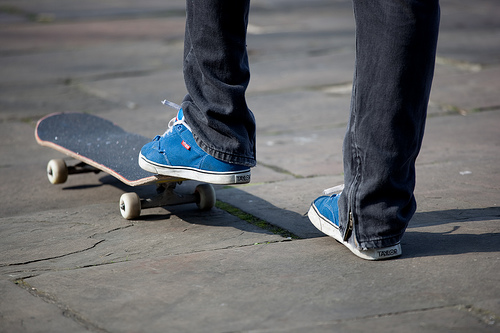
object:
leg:
[173, 0, 251, 114]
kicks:
[137, 120, 250, 185]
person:
[138, 0, 434, 260]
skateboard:
[34, 111, 216, 218]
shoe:
[137, 109, 250, 184]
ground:
[1, 1, 499, 331]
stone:
[6, 218, 496, 332]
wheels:
[118, 194, 141, 219]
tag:
[181, 140, 190, 150]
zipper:
[348, 212, 353, 230]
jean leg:
[342, 0, 438, 209]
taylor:
[376, 249, 397, 257]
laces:
[160, 98, 192, 138]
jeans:
[182, 0, 437, 250]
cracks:
[19, 237, 294, 279]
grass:
[217, 203, 297, 240]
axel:
[141, 194, 201, 209]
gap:
[218, 203, 303, 240]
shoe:
[308, 181, 405, 261]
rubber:
[308, 203, 404, 260]